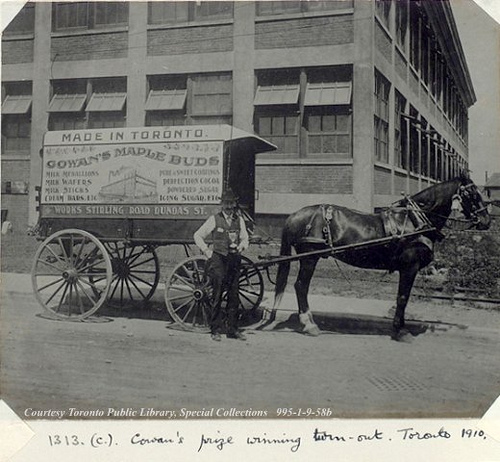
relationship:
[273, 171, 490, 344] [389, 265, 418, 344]
horse has leg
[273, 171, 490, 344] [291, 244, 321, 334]
horse has leg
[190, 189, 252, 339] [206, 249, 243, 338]
man wearing pants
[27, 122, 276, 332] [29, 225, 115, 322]
carriage has wheel